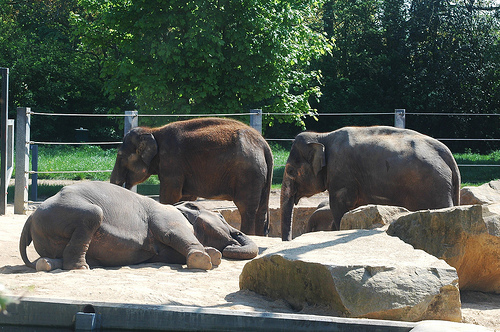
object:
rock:
[238, 229, 462, 321]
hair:
[190, 115, 223, 142]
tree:
[87, 2, 325, 137]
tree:
[0, 0, 118, 140]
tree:
[398, 1, 494, 154]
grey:
[102, 196, 144, 240]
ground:
[0, 106, 495, 332]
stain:
[283, 179, 293, 186]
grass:
[11, 123, 497, 200]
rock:
[459, 177, 500, 204]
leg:
[161, 223, 211, 270]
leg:
[202, 246, 221, 265]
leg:
[60, 206, 105, 271]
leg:
[35, 254, 62, 271]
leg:
[234, 192, 260, 235]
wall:
[252, 113, 401, 135]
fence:
[14, 108, 500, 214]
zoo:
[0, 0, 500, 332]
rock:
[340, 204, 412, 230]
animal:
[276, 125, 463, 240]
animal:
[112, 116, 273, 237]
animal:
[18, 178, 259, 271]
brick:
[15, 202, 27, 214]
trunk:
[279, 160, 302, 243]